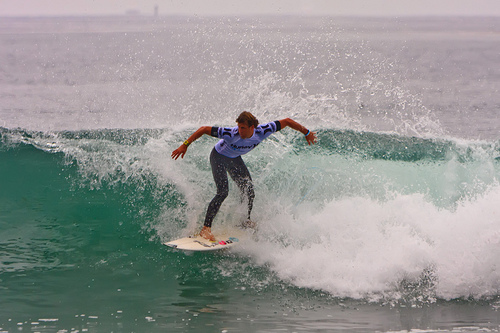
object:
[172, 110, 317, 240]
person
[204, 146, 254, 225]
pants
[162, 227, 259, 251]
surfboard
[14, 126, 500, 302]
wave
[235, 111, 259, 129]
hair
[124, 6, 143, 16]
ship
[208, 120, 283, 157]
shirt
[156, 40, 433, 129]
spray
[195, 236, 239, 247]
decals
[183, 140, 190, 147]
wristband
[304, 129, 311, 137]
bracelet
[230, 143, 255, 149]
name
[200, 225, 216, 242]
foot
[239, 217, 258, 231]
foot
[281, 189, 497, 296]
foam